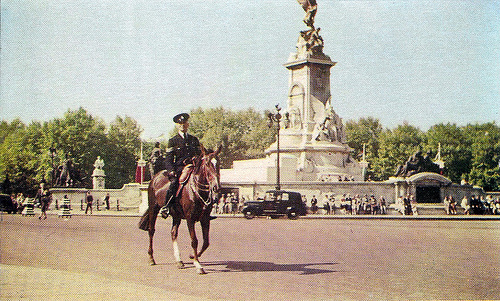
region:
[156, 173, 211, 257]
Brown and white horse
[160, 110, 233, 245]
Police officer on horse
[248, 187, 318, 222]
Black car on street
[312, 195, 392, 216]
People sitting on steps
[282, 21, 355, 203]
Statue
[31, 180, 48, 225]
Person crossing the street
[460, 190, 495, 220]
Group of people sitting together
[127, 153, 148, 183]
Red Flag in Park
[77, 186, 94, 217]
Person about to cross street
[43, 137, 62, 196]
Street Lamp in Park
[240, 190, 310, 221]
a black car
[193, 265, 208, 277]
the hoof of a horse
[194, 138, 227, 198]
the head of a horse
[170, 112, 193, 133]
the head of a man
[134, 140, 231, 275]
a horse on the road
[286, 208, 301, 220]
a black car tire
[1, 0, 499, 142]
a pale blue sky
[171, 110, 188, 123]
a black hat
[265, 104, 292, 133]
a pair of street lights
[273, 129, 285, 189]
a street light pole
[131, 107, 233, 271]
SOLDIER ON A HORSE.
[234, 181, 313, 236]
BLACK CAR PARKED.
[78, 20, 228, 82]
CLEAR SKIES.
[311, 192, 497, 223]
PEOPLE SITED WATCHING SOMETHING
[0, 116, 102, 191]
TREES IN THE BACKGROUND.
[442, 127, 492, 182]
LEAVES ARE GREEN IN COLOR .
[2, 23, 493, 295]
DAY IS VERY SUNNY.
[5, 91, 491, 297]
PICTURE IS OF A PUBLIC PLACE.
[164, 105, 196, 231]
THE MAN IS A SOLDIER.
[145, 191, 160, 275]
this is the back right leg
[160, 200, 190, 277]
this is the back left leg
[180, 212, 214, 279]
the front right leg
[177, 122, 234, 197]
a brown horse's head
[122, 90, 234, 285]
a man on a horse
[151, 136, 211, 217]
a dark black uniform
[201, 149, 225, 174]
a white head spot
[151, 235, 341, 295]
this is a shadow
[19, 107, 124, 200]
these are green trees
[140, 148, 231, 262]
THE ANIMAL IS A HORSE.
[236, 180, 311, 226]
A BLACK CAR IS PARKED.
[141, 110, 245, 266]
THE MAN IS IN A PARADE.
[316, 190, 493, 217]
A GROUP OF PEOPLE WATCHING.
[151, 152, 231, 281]
THE HORSE IS BROWN AND WHITE.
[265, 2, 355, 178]
A MONUMENT IN A PARK.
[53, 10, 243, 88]
THE SKY IS CLEAR.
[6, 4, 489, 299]
PICTURE WAS TAKEN OUTDOORS.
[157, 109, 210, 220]
an officer rides a horse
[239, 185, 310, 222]
a black patrol car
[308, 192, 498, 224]
many people sit on the edge of the monument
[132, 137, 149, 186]
this poll holds a banner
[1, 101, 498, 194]
leaves on the trees show it is summer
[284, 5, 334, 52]
the central stature of the monument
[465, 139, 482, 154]
green leaves on the tree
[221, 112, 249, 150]
green leaves on the tree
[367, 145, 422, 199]
green leaves on the tree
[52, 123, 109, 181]
green leaves on the tree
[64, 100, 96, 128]
green leaves on the tree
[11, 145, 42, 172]
green leaves on the tree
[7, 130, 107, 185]
green leaves on the tree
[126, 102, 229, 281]
Person on a horse